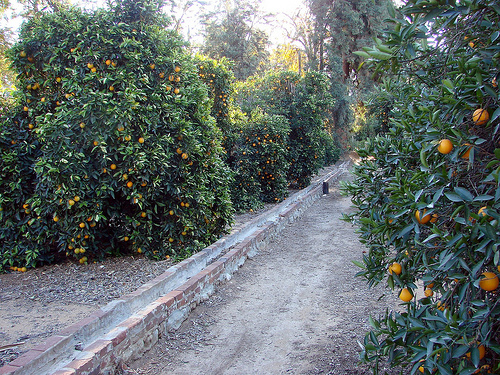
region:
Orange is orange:
[475, 267, 498, 294]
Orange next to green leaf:
[435, 137, 452, 156]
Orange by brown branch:
[470, 103, 489, 126]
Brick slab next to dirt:
[0, 167, 350, 373]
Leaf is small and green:
[420, 315, 449, 332]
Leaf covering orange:
[469, 345, 482, 367]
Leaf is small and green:
[366, 47, 393, 61]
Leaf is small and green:
[105, 152, 112, 162]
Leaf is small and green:
[87, 112, 98, 125]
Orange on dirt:
[21, 265, 26, 276]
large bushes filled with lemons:
[21, 35, 219, 246]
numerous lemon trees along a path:
[29, 1, 355, 221]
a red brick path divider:
[46, 307, 157, 354]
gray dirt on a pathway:
[246, 289, 345, 374]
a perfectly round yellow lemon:
[396, 286, 413, 303]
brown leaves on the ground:
[27, 276, 127, 318]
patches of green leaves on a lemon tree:
[71, 93, 124, 135]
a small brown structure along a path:
[318, 175, 335, 200]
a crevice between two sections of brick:
[79, 322, 105, 354]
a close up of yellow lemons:
[381, 198, 495, 358]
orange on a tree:
[433, 129, 455, 156]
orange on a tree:
[385, 258, 401, 279]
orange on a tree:
[392, 283, 415, 307]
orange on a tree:
[479, 269, 496, 294]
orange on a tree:
[467, 103, 494, 129]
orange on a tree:
[137, 133, 147, 144]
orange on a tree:
[179, 150, 189, 163]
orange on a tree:
[72, 192, 84, 204]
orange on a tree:
[77, 220, 87, 230]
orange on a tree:
[170, 61, 182, 76]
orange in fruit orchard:
[431, 138, 451, 158]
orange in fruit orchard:
[380, 259, 400, 282]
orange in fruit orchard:
[396, 289, 418, 307]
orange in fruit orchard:
[476, 268, 493, 290]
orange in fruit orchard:
[125, 182, 135, 189]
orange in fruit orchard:
[177, 150, 191, 162]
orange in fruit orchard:
[174, 87, 183, 98]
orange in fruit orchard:
[106, 160, 117, 167]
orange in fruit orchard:
[76, 220, 87, 227]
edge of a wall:
[141, 324, 148, 335]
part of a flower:
[422, 185, 444, 257]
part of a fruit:
[423, 292, 438, 301]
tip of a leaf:
[418, 229, 423, 253]